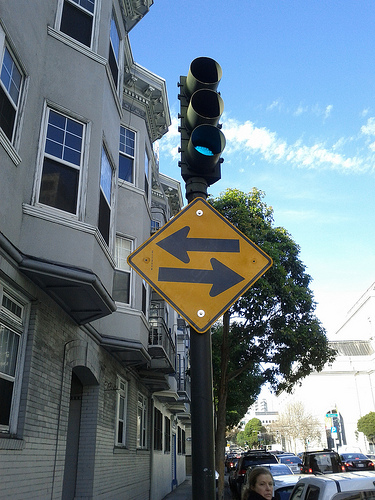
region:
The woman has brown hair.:
[239, 466, 273, 498]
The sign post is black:
[185, 304, 223, 499]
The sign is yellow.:
[129, 189, 275, 337]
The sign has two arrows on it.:
[151, 219, 249, 304]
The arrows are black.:
[152, 222, 246, 302]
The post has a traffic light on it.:
[174, 53, 224, 185]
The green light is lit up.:
[186, 126, 221, 168]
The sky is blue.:
[61, 0, 372, 333]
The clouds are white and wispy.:
[147, 72, 372, 202]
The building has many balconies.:
[0, 0, 204, 498]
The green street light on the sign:
[183, 123, 226, 170]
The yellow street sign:
[123, 196, 274, 330]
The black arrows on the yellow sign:
[154, 224, 246, 297]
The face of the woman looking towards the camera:
[240, 465, 279, 499]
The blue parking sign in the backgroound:
[329, 424, 339, 433]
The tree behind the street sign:
[187, 187, 334, 497]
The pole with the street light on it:
[186, 181, 221, 498]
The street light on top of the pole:
[174, 55, 230, 190]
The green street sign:
[321, 408, 341, 417]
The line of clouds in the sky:
[156, 90, 374, 177]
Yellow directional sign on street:
[122, 196, 295, 330]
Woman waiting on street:
[237, 467, 282, 499]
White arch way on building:
[310, 404, 365, 450]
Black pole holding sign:
[185, 342, 223, 485]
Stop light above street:
[168, 57, 238, 172]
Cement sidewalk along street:
[172, 474, 195, 498]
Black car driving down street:
[293, 445, 343, 474]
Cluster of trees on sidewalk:
[234, 419, 274, 447]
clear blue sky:
[296, 179, 360, 244]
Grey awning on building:
[335, 337, 374, 354]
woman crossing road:
[244, 458, 276, 498]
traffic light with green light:
[167, 50, 254, 270]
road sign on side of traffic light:
[113, 182, 266, 342]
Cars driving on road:
[231, 431, 373, 499]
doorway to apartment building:
[54, 327, 97, 498]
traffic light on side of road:
[161, 55, 232, 434]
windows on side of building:
[110, 369, 181, 478]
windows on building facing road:
[33, 86, 116, 261]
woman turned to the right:
[233, 458, 275, 499]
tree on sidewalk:
[159, 176, 343, 499]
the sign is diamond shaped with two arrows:
[122, 195, 269, 305]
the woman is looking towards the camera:
[245, 454, 296, 499]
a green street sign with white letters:
[312, 411, 354, 420]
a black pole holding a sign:
[173, 315, 229, 497]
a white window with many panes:
[2, 287, 26, 440]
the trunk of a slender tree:
[216, 325, 249, 469]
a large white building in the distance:
[270, 347, 373, 477]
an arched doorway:
[40, 340, 126, 489]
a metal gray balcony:
[134, 287, 193, 374]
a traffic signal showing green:
[175, 55, 229, 172]